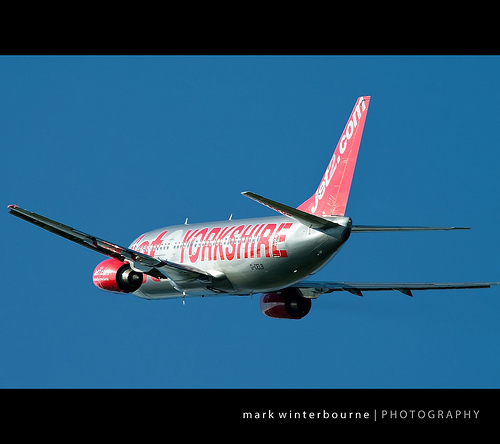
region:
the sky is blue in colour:
[83, 85, 230, 190]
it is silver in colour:
[8, 143, 358, 313]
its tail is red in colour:
[298, 78, 391, 202]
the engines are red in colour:
[59, 240, 136, 312]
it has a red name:
[178, 221, 306, 261]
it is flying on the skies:
[5, 188, 399, 320]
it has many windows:
[117, 221, 265, 251]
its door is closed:
[156, 236, 177, 259]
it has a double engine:
[76, 242, 324, 328]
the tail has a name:
[280, 95, 371, 212]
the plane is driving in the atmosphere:
[118, 193, 433, 341]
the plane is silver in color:
[109, 182, 429, 324]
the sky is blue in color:
[340, 320, 495, 381]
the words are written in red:
[198, 213, 279, 254]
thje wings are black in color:
[341, 278, 478, 293]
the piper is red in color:
[88, 264, 148, 284]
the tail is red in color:
[323, 118, 363, 207]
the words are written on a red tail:
[303, 112, 355, 204]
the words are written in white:
[288, 113, 356, 215]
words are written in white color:
[246, 408, 479, 440]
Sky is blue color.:
[55, 92, 452, 384]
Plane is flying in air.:
[30, 118, 440, 365]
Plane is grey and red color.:
[73, 135, 374, 338]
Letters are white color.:
[235, 405, 482, 420]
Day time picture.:
[15, 46, 475, 381]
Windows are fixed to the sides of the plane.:
[125, 231, 265, 251]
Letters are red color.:
[120, 222, 290, 263]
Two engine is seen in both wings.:
[85, 250, 311, 325]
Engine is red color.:
[92, 258, 317, 323]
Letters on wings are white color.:
[299, 99, 357, 212]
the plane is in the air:
[20, 89, 420, 347]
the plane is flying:
[46, 88, 433, 349]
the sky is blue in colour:
[98, 109, 175, 192]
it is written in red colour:
[134, 227, 281, 262]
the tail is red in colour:
[322, 90, 377, 206]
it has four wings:
[36, 188, 468, 375]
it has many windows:
[161, 228, 276, 244]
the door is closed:
[267, 231, 281, 260]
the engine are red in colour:
[74, 248, 139, 293]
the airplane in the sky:
[6, 94, 498, 319]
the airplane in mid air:
[7, 95, 498, 317]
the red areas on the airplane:
[6, 95, 498, 315]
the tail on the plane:
[292, 95, 369, 213]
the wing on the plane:
[6, 203, 216, 283]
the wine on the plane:
[292, 279, 499, 296]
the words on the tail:
[305, 96, 369, 216]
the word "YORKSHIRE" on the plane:
[179, 222, 291, 262]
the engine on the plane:
[92, 258, 142, 292]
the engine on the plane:
[260, 290, 312, 317]